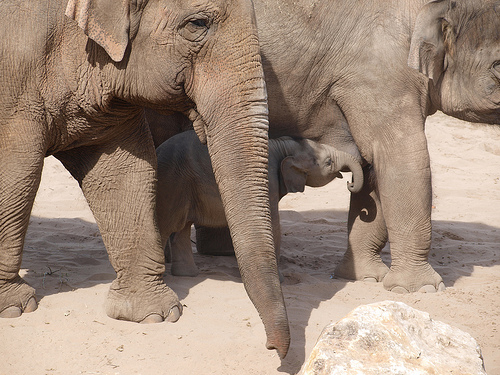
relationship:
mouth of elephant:
[170, 75, 204, 144] [1, 0, 290, 361]